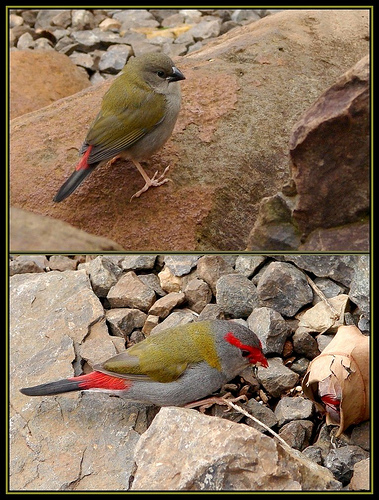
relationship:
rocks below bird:
[17, 257, 369, 342] [49, 41, 189, 228]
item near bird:
[317, 393, 340, 409] [21, 318, 268, 404]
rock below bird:
[288, 55, 371, 233] [112, 73, 170, 183]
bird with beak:
[18, 320, 269, 414] [242, 346, 273, 374]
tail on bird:
[18, 371, 128, 396] [21, 318, 268, 404]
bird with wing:
[106, 340, 239, 390] [100, 320, 221, 382]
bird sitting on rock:
[51, 52, 178, 208] [8, 9, 369, 247]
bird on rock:
[51, 52, 178, 208] [8, 9, 369, 247]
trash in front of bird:
[17, 317, 271, 415] [295, 322, 372, 434]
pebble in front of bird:
[250, 307, 289, 342] [95, 333, 247, 400]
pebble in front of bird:
[262, 364, 293, 393] [95, 333, 247, 400]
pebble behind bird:
[110, 275, 153, 299] [95, 333, 247, 400]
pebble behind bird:
[215, 268, 259, 309] [95, 333, 247, 400]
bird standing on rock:
[51, 50, 186, 202] [195, 55, 295, 137]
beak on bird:
[168, 68, 185, 84] [52, 37, 191, 201]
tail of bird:
[18, 371, 128, 396] [48, 37, 233, 223]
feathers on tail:
[74, 365, 123, 389] [20, 363, 125, 396]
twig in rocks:
[304, 275, 338, 314] [9, 256, 370, 489]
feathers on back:
[91, 320, 216, 381] [107, 319, 215, 352]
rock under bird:
[26, 246, 360, 340] [67, 41, 209, 220]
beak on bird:
[251, 358, 272, 370] [74, 320, 258, 408]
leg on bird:
[128, 144, 145, 179] [51, 50, 186, 202]